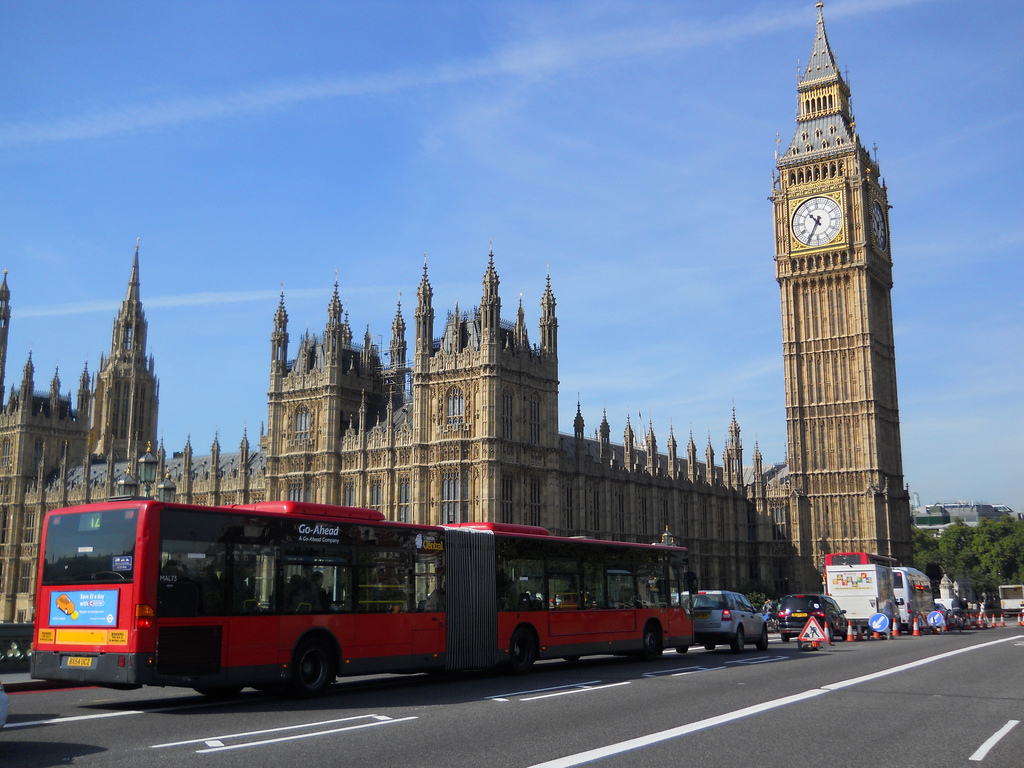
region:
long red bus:
[24, 498, 696, 702]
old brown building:
[15, 276, 785, 511]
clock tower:
[762, 46, 911, 527]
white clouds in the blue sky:
[35, 20, 127, 104]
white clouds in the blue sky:
[539, 195, 631, 249]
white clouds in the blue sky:
[676, 346, 750, 401]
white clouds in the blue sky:
[517, 156, 591, 196]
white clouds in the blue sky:
[400, 157, 442, 183]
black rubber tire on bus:
[290, 636, 335, 695]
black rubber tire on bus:
[508, 629, 540, 674]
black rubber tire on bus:
[641, 624, 660, 659]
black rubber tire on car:
[729, 632, 746, 653]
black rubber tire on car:
[754, 629, 771, 653]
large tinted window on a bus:
[42, 506, 138, 580]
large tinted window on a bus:
[159, 541, 226, 615]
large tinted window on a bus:
[499, 559, 547, 613]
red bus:
[19, 495, 677, 667]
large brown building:
[63, 232, 725, 504]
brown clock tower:
[743, 34, 953, 521]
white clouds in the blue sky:
[427, 8, 549, 86]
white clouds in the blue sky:
[498, 100, 642, 174]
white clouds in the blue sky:
[177, 205, 247, 248]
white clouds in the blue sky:
[594, 144, 686, 222]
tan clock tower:
[748, 54, 914, 536]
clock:
[784, 177, 851, 238]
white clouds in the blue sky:
[631, 256, 704, 334]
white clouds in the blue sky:
[292, 162, 370, 299]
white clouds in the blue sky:
[541, 60, 652, 188]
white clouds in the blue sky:
[295, 139, 426, 235]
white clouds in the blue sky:
[552, 157, 657, 253]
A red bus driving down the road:
[26, 492, 693, 699]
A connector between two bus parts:
[439, 524, 494, 673]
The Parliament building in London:
[3, 249, 784, 641]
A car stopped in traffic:
[695, 587, 771, 654]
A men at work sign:
[796, 614, 826, 649]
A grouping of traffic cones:
[817, 619, 865, 648]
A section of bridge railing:
[3, 619, 35, 668]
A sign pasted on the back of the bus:
[48, 587, 118, 629]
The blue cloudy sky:
[8, 193, 1020, 538]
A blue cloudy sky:
[6, 186, 1022, 516]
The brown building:
[6, 196, 952, 588]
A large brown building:
[12, 181, 977, 628]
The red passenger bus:
[32, 449, 696, 719]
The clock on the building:
[774, 190, 858, 245]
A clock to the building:
[776, 186, 849, 257]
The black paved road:
[12, 575, 1006, 766]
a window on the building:
[427, 451, 459, 489]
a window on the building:
[544, 477, 570, 520]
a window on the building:
[523, 474, 534, 500]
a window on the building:
[500, 462, 511, 514]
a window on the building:
[485, 345, 517, 464]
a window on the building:
[397, 430, 426, 514]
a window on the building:
[362, 430, 394, 535]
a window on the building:
[295, 410, 324, 486]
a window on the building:
[637, 471, 683, 549]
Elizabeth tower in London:
[771, 12, 912, 581]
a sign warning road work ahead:
[797, 618, 840, 651]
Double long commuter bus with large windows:
[4, 501, 693, 701]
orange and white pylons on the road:
[841, 615, 924, 647]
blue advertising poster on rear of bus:
[47, 581, 123, 629]